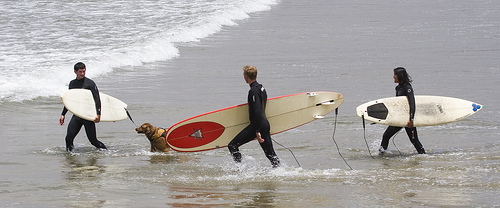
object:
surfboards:
[61, 88, 131, 123]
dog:
[133, 123, 172, 153]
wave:
[0, 0, 278, 101]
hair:
[393, 67, 412, 86]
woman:
[374, 67, 426, 156]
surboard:
[353, 94, 486, 128]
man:
[228, 65, 281, 168]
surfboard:
[163, 91, 344, 152]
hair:
[242, 65, 257, 81]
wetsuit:
[226, 80, 279, 169]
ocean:
[0, 0, 500, 208]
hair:
[73, 62, 87, 72]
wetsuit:
[378, 83, 427, 156]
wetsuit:
[59, 76, 107, 152]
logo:
[186, 128, 204, 140]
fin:
[369, 121, 376, 125]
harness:
[148, 127, 168, 141]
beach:
[0, 0, 500, 207]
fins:
[313, 115, 327, 119]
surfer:
[59, 61, 107, 151]